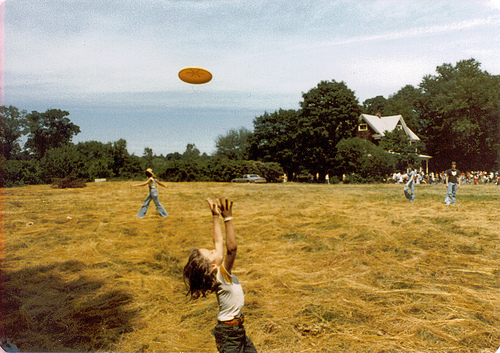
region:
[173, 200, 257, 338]
Child catching Frisbee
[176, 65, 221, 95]
Yellow Frisbee in sky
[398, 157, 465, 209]
People playing in fielding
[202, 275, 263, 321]
Girl wearing white shirt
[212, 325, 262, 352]
Girl wearing shorts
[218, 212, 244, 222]
Girl wearing wristband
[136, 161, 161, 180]
Woman wearing a hat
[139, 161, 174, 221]
Woman walking in field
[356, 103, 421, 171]
House surrounded by trees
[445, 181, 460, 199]
Guy wearing blue jeans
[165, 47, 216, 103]
Yellow Frisbee in the sky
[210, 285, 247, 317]
Girl wearing a white shirt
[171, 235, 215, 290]
Girl with blond hair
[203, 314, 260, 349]
Girl with green shorts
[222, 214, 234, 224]
Girl with wrist band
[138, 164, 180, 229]
Woman walking in the field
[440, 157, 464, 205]
Man playing in field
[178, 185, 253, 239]
Girl reaching for Frisbee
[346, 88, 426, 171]
House behind trees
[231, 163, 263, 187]
Car on the field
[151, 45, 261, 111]
a object in air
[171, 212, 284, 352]
a cute little girl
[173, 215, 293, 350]
a sweet girl standing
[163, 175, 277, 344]
a small girl standing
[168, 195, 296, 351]
a girl raising her hands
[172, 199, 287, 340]
a innocent girl raising her hands up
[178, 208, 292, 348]
a girl trying to catch an object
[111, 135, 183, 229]
a boy walking in grass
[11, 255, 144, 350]
shadow of the tree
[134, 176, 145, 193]
hand of the person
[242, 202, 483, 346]
the brown grass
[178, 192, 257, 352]
the child standing with the arms in the air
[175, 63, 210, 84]
the frisbee in the air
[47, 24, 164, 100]
the clouds in the sky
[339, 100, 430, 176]
the house in the trees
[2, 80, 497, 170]
the trees lined in the back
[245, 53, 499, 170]
the tall trees by the house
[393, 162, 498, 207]
the group of people by the house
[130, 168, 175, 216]
the person walking alone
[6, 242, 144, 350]
the shadow on the ground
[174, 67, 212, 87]
frisbee in air is orange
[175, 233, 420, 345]
grass on ground is brown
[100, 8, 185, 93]
thin clouds in sky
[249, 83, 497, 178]
grove of trees in background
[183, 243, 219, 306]
child has brown hair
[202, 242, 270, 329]
child has white shirt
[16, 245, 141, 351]
shadow left of girl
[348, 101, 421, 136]
white roof in trees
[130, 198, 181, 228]
person wears blue jeans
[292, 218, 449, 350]
dead grass around girl